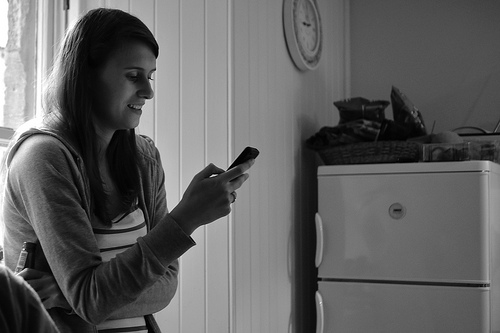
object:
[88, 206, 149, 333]
shirt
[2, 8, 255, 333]
girl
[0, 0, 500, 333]
kitchen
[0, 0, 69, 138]
window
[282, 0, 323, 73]
clock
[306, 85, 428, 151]
chips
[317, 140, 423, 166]
basket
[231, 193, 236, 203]
ring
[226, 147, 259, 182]
cell phone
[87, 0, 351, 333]
panelling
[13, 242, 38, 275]
bottle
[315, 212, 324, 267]
handle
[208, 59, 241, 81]
ground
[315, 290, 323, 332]
handle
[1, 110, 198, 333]
sweat shirt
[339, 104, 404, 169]
goodies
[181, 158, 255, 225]
hand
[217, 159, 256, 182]
finger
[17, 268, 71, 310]
hand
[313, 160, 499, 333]
freezer